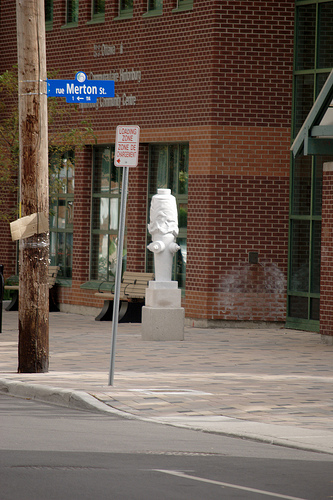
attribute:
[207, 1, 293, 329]
wall — red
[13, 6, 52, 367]
pole — brown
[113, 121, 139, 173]
traffic sign — warning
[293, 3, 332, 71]
green window — is green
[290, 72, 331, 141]
green window — is green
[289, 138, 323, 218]
green window — is green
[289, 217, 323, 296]
green window — is green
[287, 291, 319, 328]
green window — is green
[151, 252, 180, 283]
grey marble — is gray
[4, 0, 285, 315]
wall — red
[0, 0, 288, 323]
brick wall — red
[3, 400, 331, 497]
road — is gray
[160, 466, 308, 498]
line — is white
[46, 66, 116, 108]
sign — is blue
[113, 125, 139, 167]
sign — is red, is white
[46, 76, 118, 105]
sign — is blue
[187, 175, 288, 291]
brick wall — red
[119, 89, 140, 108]
word — brick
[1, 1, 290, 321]
building — red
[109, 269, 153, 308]
bench — empty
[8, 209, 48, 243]
cardboard — is brown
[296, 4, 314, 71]
window — glass, tall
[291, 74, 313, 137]
window — glass, tall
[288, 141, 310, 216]
window — glass, tall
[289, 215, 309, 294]
window — glass, tall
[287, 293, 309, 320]
window — glass, tall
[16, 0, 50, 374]
pole — light brown, dark brown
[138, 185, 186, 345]
statue — is concrete, is white, is flat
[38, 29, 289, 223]
building — community center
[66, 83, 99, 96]
letters — white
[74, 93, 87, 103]
arrow — white, pointing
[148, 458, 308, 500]
line — white, dashed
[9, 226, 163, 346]
benches — wooden